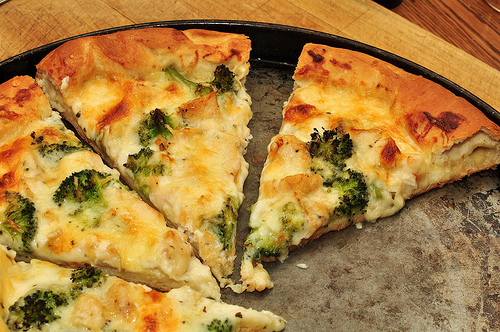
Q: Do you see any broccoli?
A: Yes, there is broccoli.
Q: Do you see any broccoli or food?
A: Yes, there is broccoli.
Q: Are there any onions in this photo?
A: No, there are no onions.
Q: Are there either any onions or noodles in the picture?
A: No, there are no onions or noodles.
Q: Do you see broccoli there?
A: Yes, there is broccoli.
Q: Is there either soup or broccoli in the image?
A: Yes, there is broccoli.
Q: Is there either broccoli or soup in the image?
A: Yes, there is broccoli.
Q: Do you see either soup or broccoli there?
A: Yes, there is broccoli.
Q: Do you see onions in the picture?
A: No, there are no onions.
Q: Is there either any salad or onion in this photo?
A: No, there are no onions or salad.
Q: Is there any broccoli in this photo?
A: Yes, there is broccoli.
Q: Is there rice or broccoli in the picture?
A: Yes, there is broccoli.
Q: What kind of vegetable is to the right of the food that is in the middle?
A: The vegetable is broccoli.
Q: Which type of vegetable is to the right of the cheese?
A: The vegetable is broccoli.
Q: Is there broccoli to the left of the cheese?
A: No, the broccoli is to the right of the cheese.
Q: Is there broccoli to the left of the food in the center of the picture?
A: No, the broccoli is to the right of the cheese.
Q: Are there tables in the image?
A: Yes, there is a table.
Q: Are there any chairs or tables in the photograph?
A: Yes, there is a table.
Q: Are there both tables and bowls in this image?
A: No, there is a table but no bowls.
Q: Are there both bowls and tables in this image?
A: No, there is a table but no bowls.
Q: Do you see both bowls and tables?
A: No, there is a table but no bowls.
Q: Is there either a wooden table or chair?
A: Yes, there is a wood table.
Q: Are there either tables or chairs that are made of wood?
A: Yes, the table is made of wood.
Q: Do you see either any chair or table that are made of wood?
A: Yes, the table is made of wood.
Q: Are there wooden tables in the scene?
A: Yes, there is a wood table.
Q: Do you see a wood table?
A: Yes, there is a wood table.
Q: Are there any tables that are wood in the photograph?
A: Yes, there is a wood table.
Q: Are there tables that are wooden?
A: Yes, there is a table that is wooden.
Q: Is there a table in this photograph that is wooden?
A: Yes, there is a table that is wooden.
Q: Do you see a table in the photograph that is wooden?
A: Yes, there is a table that is wooden.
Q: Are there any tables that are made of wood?
A: Yes, there is a table that is made of wood.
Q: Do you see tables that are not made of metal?
A: Yes, there is a table that is made of wood.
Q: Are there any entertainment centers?
A: No, there are no entertainment centers.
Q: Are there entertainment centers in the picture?
A: No, there are no entertainment centers.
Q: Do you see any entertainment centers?
A: No, there are no entertainment centers.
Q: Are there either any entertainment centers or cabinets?
A: No, there are no entertainment centers or cabinets.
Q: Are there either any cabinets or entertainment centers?
A: No, there are no entertainment centers or cabinets.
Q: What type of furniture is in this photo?
A: The furniture is a table.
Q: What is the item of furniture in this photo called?
A: The piece of furniture is a table.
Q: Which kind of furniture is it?
A: The piece of furniture is a table.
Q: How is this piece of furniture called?
A: This is a table.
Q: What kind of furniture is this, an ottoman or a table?
A: This is a table.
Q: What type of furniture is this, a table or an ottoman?
A: This is a table.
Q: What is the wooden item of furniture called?
A: The piece of furniture is a table.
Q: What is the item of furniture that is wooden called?
A: The piece of furniture is a table.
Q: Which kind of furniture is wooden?
A: The furniture is a table.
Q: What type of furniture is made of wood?
A: The furniture is a table.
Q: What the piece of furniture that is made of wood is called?
A: The piece of furniture is a table.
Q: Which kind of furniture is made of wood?
A: The furniture is a table.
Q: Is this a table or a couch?
A: This is a table.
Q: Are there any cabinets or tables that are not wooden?
A: No, there is a table but it is wooden.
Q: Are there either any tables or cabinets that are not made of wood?
A: No, there is a table but it is made of wood.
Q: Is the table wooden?
A: Yes, the table is wooden.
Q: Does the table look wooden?
A: Yes, the table is wooden.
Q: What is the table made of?
A: The table is made of wood.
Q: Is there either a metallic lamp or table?
A: No, there is a table but it is wooden.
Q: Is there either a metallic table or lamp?
A: No, there is a table but it is wooden.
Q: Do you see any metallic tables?
A: No, there is a table but it is wooden.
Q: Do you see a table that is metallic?
A: No, there is a table but it is wooden.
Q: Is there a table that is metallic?
A: No, there is a table but it is wooden.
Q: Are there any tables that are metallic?
A: No, there is a table but it is wooden.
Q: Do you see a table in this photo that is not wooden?
A: No, there is a table but it is wooden.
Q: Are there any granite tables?
A: No, there is a table but it is made of wood.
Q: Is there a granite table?
A: No, there is a table but it is made of wood.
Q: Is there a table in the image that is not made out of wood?
A: No, there is a table but it is made of wood.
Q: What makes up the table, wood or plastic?
A: The table is made of wood.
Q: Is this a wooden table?
A: Yes, this is a wooden table.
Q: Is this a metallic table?
A: No, this is a wooden table.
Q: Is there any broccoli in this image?
A: Yes, there is broccoli.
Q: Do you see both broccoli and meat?
A: No, there is broccoli but no meat.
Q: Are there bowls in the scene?
A: No, there are no bowls.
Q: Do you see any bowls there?
A: No, there are no bowls.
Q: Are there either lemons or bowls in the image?
A: No, there are no bowls or lemons.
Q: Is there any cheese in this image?
A: Yes, there is cheese.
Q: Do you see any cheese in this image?
A: Yes, there is cheese.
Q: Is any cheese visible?
A: Yes, there is cheese.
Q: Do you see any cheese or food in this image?
A: Yes, there is cheese.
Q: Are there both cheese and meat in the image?
A: No, there is cheese but no meat.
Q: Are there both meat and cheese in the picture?
A: No, there is cheese but no meat.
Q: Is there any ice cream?
A: No, there is no ice cream.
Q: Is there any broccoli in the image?
A: Yes, there is broccoli.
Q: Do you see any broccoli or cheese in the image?
A: Yes, there is broccoli.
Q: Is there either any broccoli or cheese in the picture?
A: Yes, there is broccoli.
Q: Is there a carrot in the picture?
A: No, there are no carrots.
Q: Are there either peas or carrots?
A: No, there are no carrots or peas.